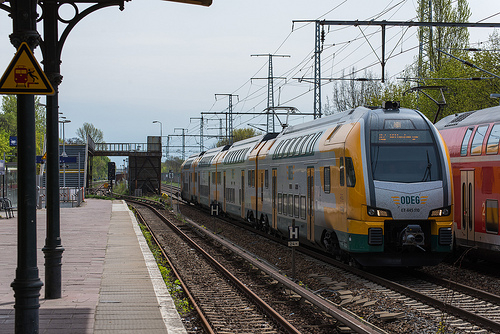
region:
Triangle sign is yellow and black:
[2, 41, 57, 101]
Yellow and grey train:
[164, 128, 461, 265]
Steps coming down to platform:
[53, 144, 97, 208]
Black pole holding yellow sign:
[3, 3, 73, 331]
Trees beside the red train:
[348, 46, 495, 114]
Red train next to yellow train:
[423, 101, 499, 258]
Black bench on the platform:
[3, 194, 21, 224]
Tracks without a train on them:
[111, 183, 258, 332]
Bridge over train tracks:
[85, 133, 186, 164]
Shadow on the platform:
[0, 289, 106, 332]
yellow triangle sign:
[0, 39, 55, 101]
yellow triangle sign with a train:
[0, 39, 56, 101]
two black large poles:
[14, 0, 65, 332]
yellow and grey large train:
[179, 101, 451, 255]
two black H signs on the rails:
[207, 199, 302, 247]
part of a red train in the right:
[432, 96, 499, 252]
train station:
[1, 138, 176, 332]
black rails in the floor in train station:
[101, 171, 498, 328]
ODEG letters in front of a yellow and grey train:
[398, 193, 425, 214]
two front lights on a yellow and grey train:
[358, 201, 456, 223]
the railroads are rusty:
[201, 136, 390, 328]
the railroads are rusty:
[165, 194, 332, 321]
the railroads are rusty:
[145, 161, 261, 328]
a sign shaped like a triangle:
[1, 42, 55, 94]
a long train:
[175, 103, 456, 265]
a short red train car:
[437, 100, 499, 248]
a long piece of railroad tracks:
[106, 170, 496, 332]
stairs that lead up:
[40, 140, 89, 202]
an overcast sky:
[5, 0, 497, 164]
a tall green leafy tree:
[413, 0, 470, 75]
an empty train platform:
[2, 193, 175, 332]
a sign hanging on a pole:
[0, 42, 55, 97]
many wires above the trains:
[147, 2, 497, 152]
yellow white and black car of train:
[263, 135, 440, 245]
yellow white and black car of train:
[214, 140, 266, 208]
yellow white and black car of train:
[185, 155, 225, 201]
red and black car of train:
[460, 115, 496, 236]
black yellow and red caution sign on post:
[3, 40, 48, 100]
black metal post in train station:
[16, 102, 43, 317]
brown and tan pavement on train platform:
[74, 215, 126, 290]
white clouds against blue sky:
[84, 28, 213, 104]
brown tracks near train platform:
[155, 214, 230, 298]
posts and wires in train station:
[273, 10, 390, 87]